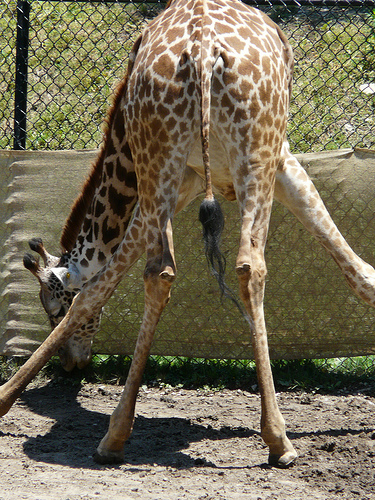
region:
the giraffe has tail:
[116, 80, 258, 278]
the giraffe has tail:
[89, 43, 239, 217]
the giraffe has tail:
[152, 57, 268, 202]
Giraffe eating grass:
[9, 5, 367, 479]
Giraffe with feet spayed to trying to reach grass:
[2, 14, 372, 469]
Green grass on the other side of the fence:
[162, 352, 372, 383]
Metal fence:
[1, 7, 367, 358]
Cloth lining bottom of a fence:
[2, 143, 372, 363]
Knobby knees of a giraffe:
[136, 258, 280, 295]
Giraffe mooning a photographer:
[27, 2, 309, 354]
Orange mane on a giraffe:
[56, 84, 123, 258]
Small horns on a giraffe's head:
[15, 234, 67, 325]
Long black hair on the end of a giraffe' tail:
[195, 191, 249, 323]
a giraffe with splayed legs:
[18, 6, 361, 437]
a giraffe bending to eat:
[15, 183, 351, 471]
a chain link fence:
[181, 311, 222, 362]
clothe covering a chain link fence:
[182, 300, 243, 377]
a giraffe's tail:
[184, 102, 261, 293]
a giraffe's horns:
[15, 230, 59, 294]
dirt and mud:
[174, 421, 230, 498]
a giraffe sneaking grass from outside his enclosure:
[51, 348, 97, 389]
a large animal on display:
[23, 21, 364, 442]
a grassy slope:
[48, 20, 89, 96]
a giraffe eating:
[6, 5, 374, 457]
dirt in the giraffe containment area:
[0, 376, 369, 497]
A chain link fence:
[0, 3, 372, 378]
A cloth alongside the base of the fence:
[4, 133, 373, 360]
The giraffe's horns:
[21, 228, 52, 283]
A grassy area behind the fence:
[10, 10, 373, 366]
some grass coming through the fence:
[0, 367, 370, 394]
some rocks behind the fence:
[336, 79, 370, 141]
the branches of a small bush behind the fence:
[355, 14, 373, 79]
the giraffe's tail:
[180, 62, 249, 319]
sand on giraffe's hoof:
[244, 449, 305, 472]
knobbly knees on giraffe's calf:
[218, 253, 271, 280]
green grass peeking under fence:
[177, 357, 242, 380]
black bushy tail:
[194, 197, 235, 261]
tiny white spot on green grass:
[333, 349, 366, 366]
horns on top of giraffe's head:
[15, 228, 51, 280]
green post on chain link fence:
[7, 98, 39, 130]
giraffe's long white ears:
[47, 256, 75, 290]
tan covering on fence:
[6, 127, 85, 200]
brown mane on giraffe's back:
[68, 135, 99, 241]